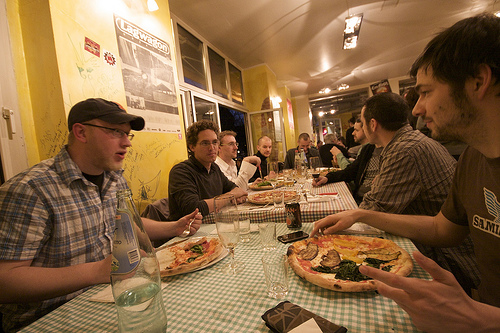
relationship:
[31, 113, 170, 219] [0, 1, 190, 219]
writing on wall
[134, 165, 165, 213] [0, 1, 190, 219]
drawing on wall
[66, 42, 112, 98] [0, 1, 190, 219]
drawing on wall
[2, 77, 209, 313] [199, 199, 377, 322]
man sitting at table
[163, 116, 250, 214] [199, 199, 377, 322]
man sitting at table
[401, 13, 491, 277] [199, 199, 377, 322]
person sitting at table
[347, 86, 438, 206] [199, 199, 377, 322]
person sitting at table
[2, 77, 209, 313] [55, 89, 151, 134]
man wearing cap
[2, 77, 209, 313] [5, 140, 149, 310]
man wearing shirt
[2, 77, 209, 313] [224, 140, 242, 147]
man wearing glasses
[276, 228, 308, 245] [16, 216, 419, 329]
cellphone on table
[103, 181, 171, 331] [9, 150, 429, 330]
bottle on table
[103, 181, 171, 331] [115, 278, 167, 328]
bottle of water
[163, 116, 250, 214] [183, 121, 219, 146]
man with hair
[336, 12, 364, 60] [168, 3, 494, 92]
light hanging on ceiling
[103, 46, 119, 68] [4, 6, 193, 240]
picture on wall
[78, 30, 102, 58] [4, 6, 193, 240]
picture on wall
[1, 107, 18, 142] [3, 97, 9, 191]
knob on window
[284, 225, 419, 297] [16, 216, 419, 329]
pizza on table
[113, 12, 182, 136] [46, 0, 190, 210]
poster on wall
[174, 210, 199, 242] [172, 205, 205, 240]
fork in hand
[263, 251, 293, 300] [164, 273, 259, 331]
glass on table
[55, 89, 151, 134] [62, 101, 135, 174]
cap on head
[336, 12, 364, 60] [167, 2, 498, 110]
light hanging from ceiling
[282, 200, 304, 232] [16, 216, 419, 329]
can on table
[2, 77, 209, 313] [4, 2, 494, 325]
man in restaurant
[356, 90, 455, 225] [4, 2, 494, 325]
person in restaurant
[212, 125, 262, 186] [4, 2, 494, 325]
person in restaurant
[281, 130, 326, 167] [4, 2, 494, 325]
person in restaurant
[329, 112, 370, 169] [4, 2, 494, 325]
person in restaurant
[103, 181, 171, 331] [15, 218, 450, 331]
bottle sitting on table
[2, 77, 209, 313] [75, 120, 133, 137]
man wearing glasses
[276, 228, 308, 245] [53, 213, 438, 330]
cellphone sitting on table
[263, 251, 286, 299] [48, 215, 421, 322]
glass sitting on table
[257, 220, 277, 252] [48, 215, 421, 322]
glass sitting on table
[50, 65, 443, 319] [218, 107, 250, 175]
establishment has open door